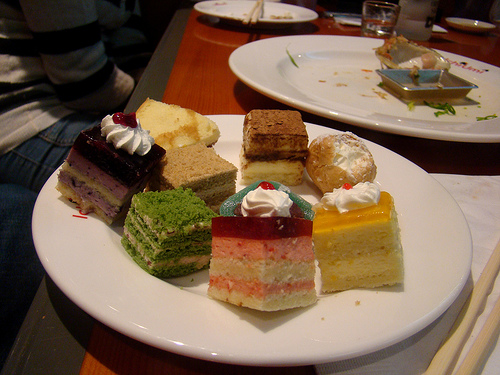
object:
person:
[1, 0, 148, 210]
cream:
[240, 186, 294, 217]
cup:
[375, 69, 478, 100]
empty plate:
[194, 0, 319, 23]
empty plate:
[228, 35, 500, 143]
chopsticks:
[242, 0, 263, 24]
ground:
[162, 0, 500, 176]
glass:
[360, 0, 400, 39]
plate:
[31, 115, 473, 367]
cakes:
[54, 97, 404, 312]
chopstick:
[422, 241, 499, 375]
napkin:
[314, 173, 499, 374]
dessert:
[120, 186, 220, 277]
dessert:
[310, 191, 405, 293]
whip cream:
[319, 181, 380, 214]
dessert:
[207, 215, 318, 311]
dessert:
[239, 109, 308, 186]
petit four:
[199, 184, 320, 309]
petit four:
[156, 142, 238, 219]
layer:
[206, 286, 317, 311]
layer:
[209, 273, 315, 299]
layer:
[209, 257, 316, 282]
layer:
[211, 236, 313, 260]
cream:
[100, 114, 155, 156]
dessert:
[55, 123, 166, 225]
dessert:
[306, 131, 377, 194]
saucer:
[445, 17, 492, 31]